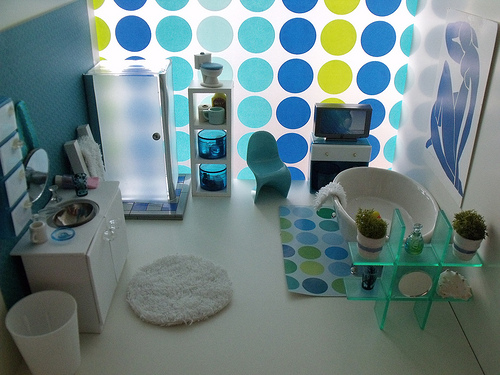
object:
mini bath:
[332, 166, 440, 245]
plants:
[452, 209, 489, 240]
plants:
[354, 207, 389, 239]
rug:
[125, 253, 233, 327]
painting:
[422, 6, 499, 208]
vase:
[404, 223, 424, 256]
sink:
[47, 198, 99, 228]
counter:
[8, 180, 128, 334]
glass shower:
[81, 59, 177, 205]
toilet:
[194, 52, 223, 88]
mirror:
[23, 148, 50, 203]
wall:
[89, 0, 420, 180]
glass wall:
[86, 0, 418, 179]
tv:
[313, 103, 373, 142]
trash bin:
[4, 290, 81, 374]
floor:
[0, 176, 485, 375]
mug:
[29, 221, 48, 245]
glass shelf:
[343, 208, 483, 330]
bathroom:
[0, 0, 497, 374]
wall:
[392, 0, 499, 375]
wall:
[0, 0, 95, 374]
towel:
[312, 181, 347, 210]